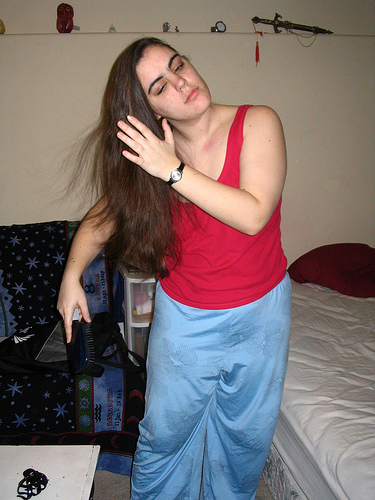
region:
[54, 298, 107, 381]
woman with a brush in her hand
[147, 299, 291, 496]
woman with blue hands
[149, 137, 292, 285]
woman with red shirt on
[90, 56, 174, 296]
woman with brown hair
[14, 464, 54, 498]
black tape on a table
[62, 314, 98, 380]
person holding a blue brush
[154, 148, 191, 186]
woman wearing a wrist watch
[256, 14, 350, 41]
sword on the wall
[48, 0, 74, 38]
owl on the shelf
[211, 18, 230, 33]
clock on the shelf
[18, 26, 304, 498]
woman is brushing her hair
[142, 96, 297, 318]
woman's shirt is red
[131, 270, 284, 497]
woman's pants are blue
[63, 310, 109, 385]
woman holding a brush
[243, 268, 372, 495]
bed has no sheet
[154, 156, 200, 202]
woman wearing a watch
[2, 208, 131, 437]
towel is blue and black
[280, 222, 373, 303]
the pillow is red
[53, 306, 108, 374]
the brush is blue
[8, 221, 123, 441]
stars on the towel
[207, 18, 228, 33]
a wrist watch sitting on a shelf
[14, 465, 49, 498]
a black claw hair clip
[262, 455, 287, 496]
a box spring that sits on the floor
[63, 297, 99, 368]
the woman is holding a hairbrush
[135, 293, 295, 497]
woman is wearing blue pj pants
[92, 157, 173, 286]
long brown hair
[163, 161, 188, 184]
wrist watch being worn by the woman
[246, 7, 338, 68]
a small sword being displayed on a shelf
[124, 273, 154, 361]
a plastic storage unit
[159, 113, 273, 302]
red tank top being worn by the woman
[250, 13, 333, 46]
a knife on the wall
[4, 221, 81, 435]
blanket with blue stars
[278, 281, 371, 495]
white sheet on the bed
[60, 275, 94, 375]
hair brush in the girl's hand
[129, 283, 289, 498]
blue pajama pants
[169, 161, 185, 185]
a black wrist watch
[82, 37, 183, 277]
girl has long brown hair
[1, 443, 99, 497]
table top is white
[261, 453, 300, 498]
the box spring has flowers on it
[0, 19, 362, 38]
a shelf with collectables on it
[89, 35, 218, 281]
the girl has long brown hair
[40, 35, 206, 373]
the girl is brushing her hair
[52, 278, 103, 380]
a hair brush is in the girl's hand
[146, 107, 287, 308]
the girl has a red tank top on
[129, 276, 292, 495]
a blue flowered skirt is on the girl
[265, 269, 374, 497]
a bed pad cover is on the bed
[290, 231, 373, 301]
a red pillow is on the bed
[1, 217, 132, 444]
a blanket is on a chair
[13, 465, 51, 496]
a black hair clip is on the table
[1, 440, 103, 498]
a white table is in the room